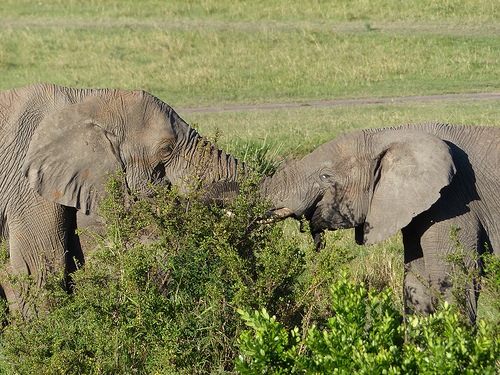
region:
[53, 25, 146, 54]
short green and brown grass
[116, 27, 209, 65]
short green and brown grass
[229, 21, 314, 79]
short green and brown grass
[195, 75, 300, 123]
short green and brown grass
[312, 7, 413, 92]
short green and brown grass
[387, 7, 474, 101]
short green and brown grass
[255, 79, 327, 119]
short green and brown grass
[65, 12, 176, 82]
short green and brown grass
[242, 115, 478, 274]
elephant eating green food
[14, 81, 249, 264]
elephant eating green branches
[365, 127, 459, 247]
left ear of a gray elephant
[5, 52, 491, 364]
front of two gray elephants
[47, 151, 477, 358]
green foliage in front of two gray elephants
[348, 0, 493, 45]
gray pathway in green grass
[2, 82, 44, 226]
wrinkled gray skin on an elephant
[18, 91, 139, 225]
gray right ear of an elephant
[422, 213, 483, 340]
front left leg of an elephant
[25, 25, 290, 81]
brown and green overgrown grass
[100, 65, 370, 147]
top of head of two gray elephants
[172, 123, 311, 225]
portions of two gray elephant trunks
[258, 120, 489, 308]
gray elephant eating branch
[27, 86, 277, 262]
gray elephant eating branch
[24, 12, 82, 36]
short green and brown grass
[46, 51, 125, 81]
short green and brown grass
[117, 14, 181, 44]
short green and brown grass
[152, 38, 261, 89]
short green and brown grass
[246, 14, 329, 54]
short green and brown grass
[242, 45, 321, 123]
short green and brown grass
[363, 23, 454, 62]
short green and brown grass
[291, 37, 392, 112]
short green and brown grass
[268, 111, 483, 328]
large gray elephant on plain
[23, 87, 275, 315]
large gray elephant on plain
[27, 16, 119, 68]
short green and yellow grass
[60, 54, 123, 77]
short green and yellow grass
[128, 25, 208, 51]
short green and yellow grass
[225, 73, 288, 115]
short green and yellow grass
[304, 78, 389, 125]
short green and yellow grass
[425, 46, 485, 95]
short green and yellow grass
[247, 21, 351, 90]
short green and yellow grass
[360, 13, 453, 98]
short green and yellow grass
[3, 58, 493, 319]
Elephants crossing trunks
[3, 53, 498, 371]
Elephants in the sunlight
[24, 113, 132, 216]
ear of an african elephant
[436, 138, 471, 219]
shadow from the ear of an elephant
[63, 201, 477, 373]
green shrubs near elephants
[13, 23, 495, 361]
elephants in a field of green near shrubbery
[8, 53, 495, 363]
elephants in a field of grass near some bushes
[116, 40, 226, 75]
green and yellow grasses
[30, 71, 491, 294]
two elephants eat from shrubbery